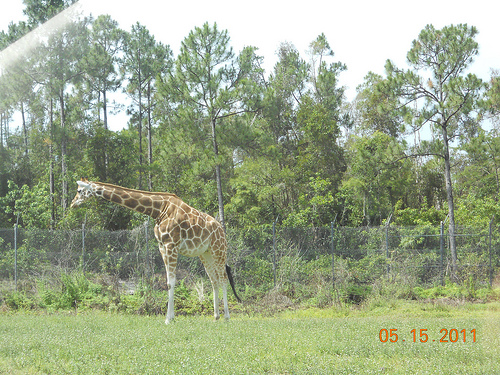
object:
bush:
[0, 252, 479, 309]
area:
[0, 33, 500, 375]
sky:
[139, 4, 463, 51]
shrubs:
[0, 255, 497, 311]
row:
[22, 259, 466, 292]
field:
[0, 305, 500, 375]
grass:
[0, 316, 500, 375]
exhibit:
[37, 50, 457, 304]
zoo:
[0, 0, 500, 374]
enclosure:
[0, 70, 500, 332]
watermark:
[372, 326, 479, 347]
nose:
[72, 206, 81, 212]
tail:
[225, 250, 249, 307]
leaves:
[0, 29, 499, 203]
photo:
[373, 321, 483, 341]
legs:
[156, 248, 250, 334]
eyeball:
[73, 186, 93, 194]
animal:
[66, 167, 253, 335]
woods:
[1, 0, 482, 285]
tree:
[0, 12, 500, 257]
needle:
[229, 46, 233, 54]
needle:
[227, 36, 230, 44]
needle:
[204, 23, 206, 29]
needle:
[194, 52, 195, 54]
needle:
[183, 89, 186, 91]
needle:
[471, 44, 474, 50]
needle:
[452, 35, 455, 41]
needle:
[413, 40, 415, 45]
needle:
[407, 56, 410, 61]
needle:
[443, 84, 444, 89]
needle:
[100, 16, 101, 20]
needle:
[114, 22, 115, 25]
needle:
[105, 14, 106, 18]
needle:
[96, 34, 97, 38]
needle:
[108, 22, 110, 27]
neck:
[90, 180, 174, 221]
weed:
[32, 272, 46, 303]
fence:
[8, 222, 497, 302]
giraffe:
[68, 171, 248, 323]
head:
[64, 173, 105, 214]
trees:
[0, 0, 500, 242]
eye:
[67, 176, 89, 195]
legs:
[156, 239, 235, 329]